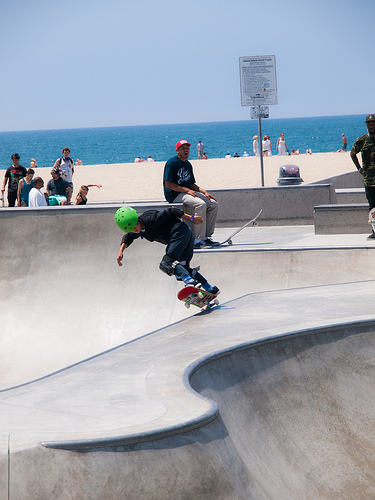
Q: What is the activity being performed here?
A: Skateboarding.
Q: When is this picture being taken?
A: Daytime.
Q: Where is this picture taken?
A: Skatepark.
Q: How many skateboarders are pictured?
A: Four.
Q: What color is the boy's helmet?
A: Green.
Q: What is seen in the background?
A: The ocean.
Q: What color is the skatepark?
A: Grey.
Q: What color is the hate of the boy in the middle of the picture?
A: Red.